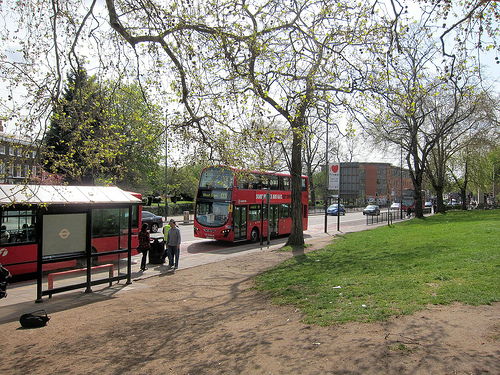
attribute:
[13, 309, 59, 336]
backpack — black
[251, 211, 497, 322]
grass — green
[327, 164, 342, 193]
banner — white, red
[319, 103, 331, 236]
post — light, tall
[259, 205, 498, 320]
grass — short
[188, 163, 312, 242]
bus — twin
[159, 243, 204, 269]
jeans — blue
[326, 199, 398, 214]
cars — 3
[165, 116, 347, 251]
bus — red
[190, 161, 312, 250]
bus — front of, double-decker, red, double decker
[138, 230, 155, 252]
coat — checkered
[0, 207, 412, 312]
road — tarmacked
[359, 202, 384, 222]
car — black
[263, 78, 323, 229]
tree — branchy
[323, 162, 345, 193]
sign — white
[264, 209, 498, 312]
area — open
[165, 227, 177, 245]
shirt — gray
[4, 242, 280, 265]
sidewalk — gray, concrete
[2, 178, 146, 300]
stop — bus